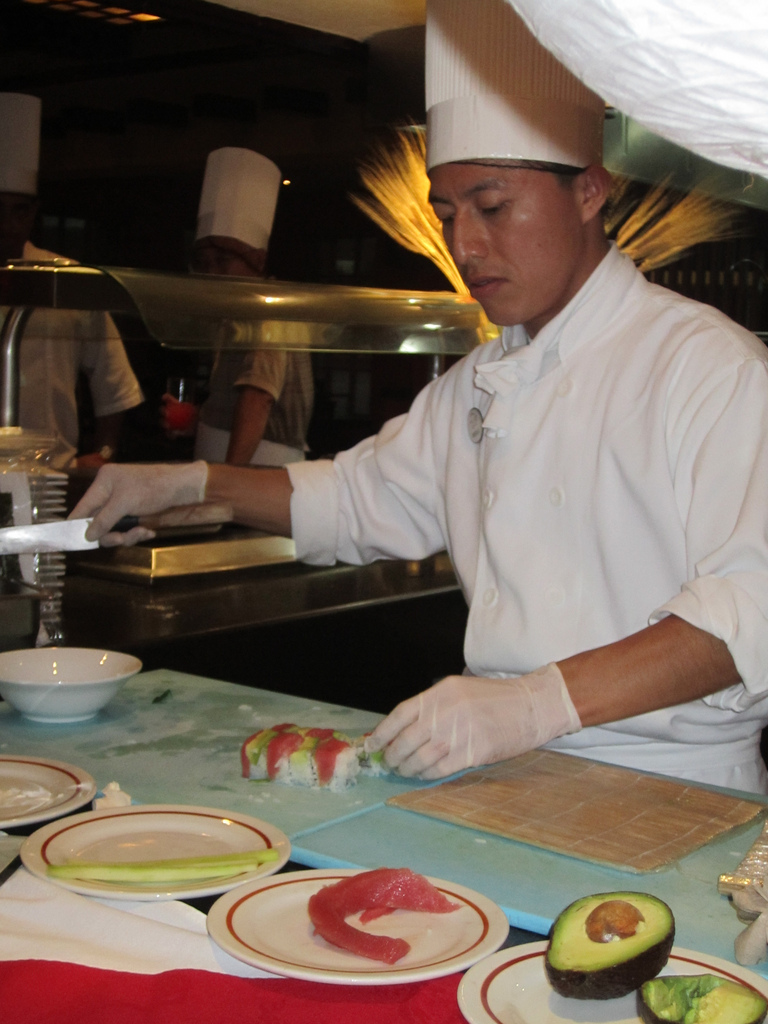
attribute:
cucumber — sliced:
[52, 851, 285, 881]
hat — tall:
[424, 1, 606, 168]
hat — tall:
[435, 7, 594, 164]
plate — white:
[454, 935, 743, 1020]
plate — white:
[458, 935, 738, 1011]